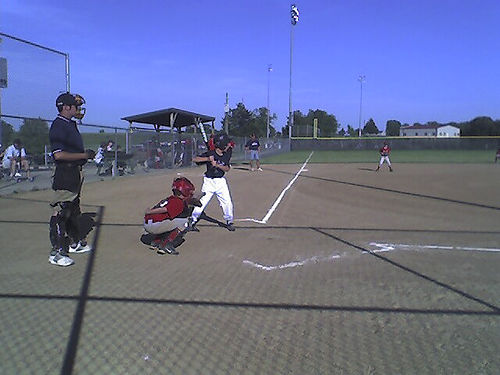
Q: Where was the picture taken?
A: It was taken at the field.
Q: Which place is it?
A: It is a field.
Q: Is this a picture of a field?
A: Yes, it is showing a field.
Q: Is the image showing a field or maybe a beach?
A: It is showing a field.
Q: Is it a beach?
A: No, it is a field.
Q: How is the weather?
A: It is cloudless.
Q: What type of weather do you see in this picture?
A: It is cloudless.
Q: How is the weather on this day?
A: It is cloudless.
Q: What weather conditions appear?
A: It is cloudless.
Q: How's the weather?
A: It is cloudless.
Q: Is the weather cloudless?
A: Yes, it is cloudless.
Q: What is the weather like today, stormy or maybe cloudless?
A: It is cloudless.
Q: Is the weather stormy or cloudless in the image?
A: It is cloudless.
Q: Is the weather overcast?
A: No, it is cloudless.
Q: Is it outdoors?
A: Yes, it is outdoors.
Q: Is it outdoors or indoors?
A: It is outdoors.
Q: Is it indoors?
A: No, it is outdoors.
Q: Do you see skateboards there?
A: No, there are no skateboards.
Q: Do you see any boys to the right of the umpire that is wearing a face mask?
A: Yes, there is a boy to the right of the umpire.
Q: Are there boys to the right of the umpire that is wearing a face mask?
A: Yes, there is a boy to the right of the umpire.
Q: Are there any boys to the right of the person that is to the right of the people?
A: Yes, there is a boy to the right of the umpire.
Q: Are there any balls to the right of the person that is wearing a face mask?
A: No, there is a boy to the right of the umpire.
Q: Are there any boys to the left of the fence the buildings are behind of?
A: Yes, there is a boy to the left of the fence.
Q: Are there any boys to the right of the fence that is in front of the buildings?
A: No, the boy is to the left of the fence.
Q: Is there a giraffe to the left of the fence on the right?
A: No, there is a boy to the left of the fence.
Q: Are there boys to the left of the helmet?
A: No, the boy is to the right of the helmet.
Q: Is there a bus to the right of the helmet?
A: No, there is a boy to the right of the helmet.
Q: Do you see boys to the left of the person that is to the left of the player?
A: Yes, there is a boy to the left of the person.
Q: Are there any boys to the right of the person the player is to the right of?
A: No, the boy is to the left of the person.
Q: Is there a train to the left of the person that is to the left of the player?
A: No, there is a boy to the left of the person.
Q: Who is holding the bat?
A: The boy is holding the bat.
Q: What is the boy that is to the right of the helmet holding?
A: The boy is holding the bat.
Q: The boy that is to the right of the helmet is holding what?
A: The boy is holding the bat.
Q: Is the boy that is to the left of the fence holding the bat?
A: Yes, the boy is holding the bat.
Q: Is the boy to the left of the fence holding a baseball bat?
A: No, the boy is holding the bat.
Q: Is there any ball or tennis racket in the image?
A: No, there are no balls or rackets.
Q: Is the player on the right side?
A: Yes, the player is on the right of the image.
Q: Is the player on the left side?
A: No, the player is on the right of the image.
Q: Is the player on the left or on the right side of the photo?
A: The player is on the right of the image.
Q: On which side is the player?
A: The player is on the right of the image.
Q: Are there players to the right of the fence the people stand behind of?
A: Yes, there is a player to the right of the fence.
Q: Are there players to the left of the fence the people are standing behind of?
A: No, the player is to the right of the fence.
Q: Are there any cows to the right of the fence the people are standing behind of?
A: No, there is a player to the right of the fence.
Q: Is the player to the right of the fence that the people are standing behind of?
A: Yes, the player is to the right of the fence.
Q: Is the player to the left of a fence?
A: No, the player is to the right of a fence.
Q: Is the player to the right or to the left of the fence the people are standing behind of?
A: The player is to the right of the fence.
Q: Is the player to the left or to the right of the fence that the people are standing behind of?
A: The player is to the right of the fence.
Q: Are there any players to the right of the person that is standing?
A: Yes, there is a player to the right of the person.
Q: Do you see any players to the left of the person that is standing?
A: No, the player is to the right of the person.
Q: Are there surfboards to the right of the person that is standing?
A: No, there is a player to the right of the person.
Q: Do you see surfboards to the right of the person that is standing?
A: No, there is a player to the right of the person.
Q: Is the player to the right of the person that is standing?
A: Yes, the player is to the right of the person.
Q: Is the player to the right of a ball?
A: No, the player is to the right of the person.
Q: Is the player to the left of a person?
A: No, the player is to the right of a person.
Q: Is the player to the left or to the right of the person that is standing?
A: The player is to the right of the person.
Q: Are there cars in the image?
A: No, there are no cars.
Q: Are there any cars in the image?
A: No, there are no cars.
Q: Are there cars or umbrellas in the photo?
A: No, there are no cars or umbrellas.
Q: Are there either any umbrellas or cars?
A: No, there are no cars or umbrellas.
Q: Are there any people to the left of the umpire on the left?
A: Yes, there are people to the left of the umpire.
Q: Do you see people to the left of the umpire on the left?
A: Yes, there are people to the left of the umpire.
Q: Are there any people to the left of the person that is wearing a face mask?
A: Yes, there are people to the left of the umpire.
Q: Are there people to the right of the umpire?
A: No, the people are to the left of the umpire.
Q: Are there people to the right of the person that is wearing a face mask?
A: No, the people are to the left of the umpire.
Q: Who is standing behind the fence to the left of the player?
A: The people are standing behind the fence.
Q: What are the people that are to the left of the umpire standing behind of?
A: The people are standing behind the fence.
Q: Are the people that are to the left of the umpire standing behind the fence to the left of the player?
A: Yes, the people are standing behind the fence.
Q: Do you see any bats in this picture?
A: Yes, there is a bat.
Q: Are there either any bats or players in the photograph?
A: Yes, there is a bat.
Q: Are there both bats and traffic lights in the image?
A: No, there is a bat but no traffic lights.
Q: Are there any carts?
A: No, there are no carts.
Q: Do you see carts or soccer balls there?
A: No, there are no carts or soccer balls.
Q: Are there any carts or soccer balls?
A: No, there are no carts or soccer balls.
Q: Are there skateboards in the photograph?
A: No, there are no skateboards.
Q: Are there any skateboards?
A: No, there are no skateboards.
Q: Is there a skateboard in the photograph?
A: No, there are no skateboards.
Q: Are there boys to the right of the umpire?
A: Yes, there is a boy to the right of the umpire.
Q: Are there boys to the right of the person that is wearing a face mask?
A: Yes, there is a boy to the right of the umpire.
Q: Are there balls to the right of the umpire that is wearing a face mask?
A: No, there is a boy to the right of the umpire.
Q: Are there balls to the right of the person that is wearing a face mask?
A: No, there is a boy to the right of the umpire.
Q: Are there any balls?
A: No, there are no balls.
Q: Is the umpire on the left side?
A: Yes, the umpire is on the left of the image.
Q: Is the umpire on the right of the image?
A: No, the umpire is on the left of the image.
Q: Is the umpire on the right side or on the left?
A: The umpire is on the left of the image.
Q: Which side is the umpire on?
A: The umpire is on the left of the image.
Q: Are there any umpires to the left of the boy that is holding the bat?
A: Yes, there is an umpire to the left of the boy.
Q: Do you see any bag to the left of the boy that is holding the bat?
A: No, there is an umpire to the left of the boy.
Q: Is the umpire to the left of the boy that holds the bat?
A: Yes, the umpire is to the left of the boy.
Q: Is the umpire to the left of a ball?
A: No, the umpire is to the left of the boy.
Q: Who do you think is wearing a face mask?
A: The umpire is wearing a face mask.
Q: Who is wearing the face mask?
A: The umpire is wearing a face mask.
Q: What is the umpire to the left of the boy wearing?
A: The umpire is wearing a face mask.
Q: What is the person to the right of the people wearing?
A: The umpire is wearing a face mask.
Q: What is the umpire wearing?
A: The umpire is wearing a face mask.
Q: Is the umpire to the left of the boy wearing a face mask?
A: Yes, the umpire is wearing a face mask.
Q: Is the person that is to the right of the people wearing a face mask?
A: Yes, the umpire is wearing a face mask.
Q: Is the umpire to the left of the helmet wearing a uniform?
A: No, the umpire is wearing a face mask.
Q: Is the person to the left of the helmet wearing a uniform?
A: No, the umpire is wearing a face mask.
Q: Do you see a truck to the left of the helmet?
A: No, there is an umpire to the left of the helmet.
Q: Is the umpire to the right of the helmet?
A: No, the umpire is to the left of the helmet.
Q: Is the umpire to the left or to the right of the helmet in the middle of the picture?
A: The umpire is to the left of the helmet.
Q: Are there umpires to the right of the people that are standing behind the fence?
A: Yes, there is an umpire to the right of the people.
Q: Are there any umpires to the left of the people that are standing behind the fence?
A: No, the umpire is to the right of the people.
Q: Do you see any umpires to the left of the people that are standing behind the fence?
A: No, the umpire is to the right of the people.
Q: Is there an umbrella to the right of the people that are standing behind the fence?
A: No, there is an umpire to the right of the people.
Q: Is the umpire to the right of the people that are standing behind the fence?
A: Yes, the umpire is to the right of the people.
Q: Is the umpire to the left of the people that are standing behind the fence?
A: No, the umpire is to the right of the people.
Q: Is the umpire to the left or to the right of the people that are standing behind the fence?
A: The umpire is to the right of the people.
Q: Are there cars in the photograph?
A: No, there are no cars.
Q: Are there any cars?
A: No, there are no cars.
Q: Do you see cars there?
A: No, there are no cars.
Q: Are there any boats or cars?
A: No, there are no cars or boats.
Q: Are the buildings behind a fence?
A: Yes, the buildings are behind a fence.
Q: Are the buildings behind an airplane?
A: No, the buildings are behind a fence.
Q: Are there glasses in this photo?
A: No, there are no glasses.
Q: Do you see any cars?
A: No, there are no cars.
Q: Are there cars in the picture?
A: No, there are no cars.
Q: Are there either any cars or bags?
A: No, there are no cars or bags.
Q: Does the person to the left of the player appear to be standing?
A: Yes, the person is standing.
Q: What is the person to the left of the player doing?
A: The person is standing.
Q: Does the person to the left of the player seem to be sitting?
A: No, the person is standing.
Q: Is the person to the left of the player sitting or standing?
A: The person is standing.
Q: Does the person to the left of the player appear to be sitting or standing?
A: The person is standing.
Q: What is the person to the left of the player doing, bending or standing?
A: The person is standing.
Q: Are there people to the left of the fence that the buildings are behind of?
A: Yes, there is a person to the left of the fence.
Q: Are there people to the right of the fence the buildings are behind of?
A: No, the person is to the left of the fence.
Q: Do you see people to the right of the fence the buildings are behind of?
A: No, the person is to the left of the fence.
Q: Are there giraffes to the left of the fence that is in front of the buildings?
A: No, there is a person to the left of the fence.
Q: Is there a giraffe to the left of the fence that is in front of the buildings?
A: No, there is a person to the left of the fence.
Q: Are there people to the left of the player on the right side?
A: Yes, there is a person to the left of the player.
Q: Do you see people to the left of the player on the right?
A: Yes, there is a person to the left of the player.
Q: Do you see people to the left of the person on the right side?
A: Yes, there is a person to the left of the player.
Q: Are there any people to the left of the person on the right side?
A: Yes, there is a person to the left of the player.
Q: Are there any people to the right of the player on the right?
A: No, the person is to the left of the player.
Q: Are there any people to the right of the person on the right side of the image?
A: No, the person is to the left of the player.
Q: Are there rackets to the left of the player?
A: No, there is a person to the left of the player.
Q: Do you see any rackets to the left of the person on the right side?
A: No, there is a person to the left of the player.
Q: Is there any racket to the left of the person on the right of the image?
A: No, there is a person to the left of the player.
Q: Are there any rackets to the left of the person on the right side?
A: No, there is a person to the left of the player.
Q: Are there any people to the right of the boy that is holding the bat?
A: Yes, there is a person to the right of the boy.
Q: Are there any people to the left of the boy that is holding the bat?
A: No, the person is to the right of the boy.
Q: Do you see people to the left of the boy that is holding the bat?
A: No, the person is to the right of the boy.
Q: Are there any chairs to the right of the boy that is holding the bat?
A: No, there is a person to the right of the boy.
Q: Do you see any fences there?
A: Yes, there is a fence.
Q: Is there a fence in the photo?
A: Yes, there is a fence.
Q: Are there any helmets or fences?
A: Yes, there is a fence.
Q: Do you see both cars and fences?
A: No, there is a fence but no cars.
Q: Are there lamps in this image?
A: No, there are no lamps.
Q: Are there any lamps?
A: No, there are no lamps.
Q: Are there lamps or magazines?
A: No, there are no lamps or magazines.